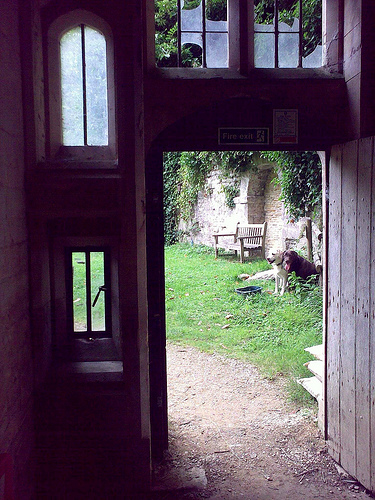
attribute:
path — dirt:
[74, 324, 372, 499]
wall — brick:
[165, 152, 321, 282]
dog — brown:
[279, 247, 319, 285]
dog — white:
[243, 247, 289, 298]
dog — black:
[269, 247, 286, 292]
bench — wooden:
[210, 217, 269, 264]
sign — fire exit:
[216, 127, 269, 144]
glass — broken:
[154, 0, 227, 68]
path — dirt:
[167, 339, 372, 486]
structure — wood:
[327, 137, 374, 494]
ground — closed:
[321, 112, 340, 137]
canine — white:
[265, 246, 290, 295]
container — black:
[230, 281, 273, 297]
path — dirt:
[174, 325, 311, 470]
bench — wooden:
[199, 211, 298, 286]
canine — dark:
[281, 248, 316, 282]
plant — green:
[161, 148, 328, 254]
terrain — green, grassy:
[166, 245, 324, 374]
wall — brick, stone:
[192, 170, 278, 198]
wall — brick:
[176, 161, 311, 266]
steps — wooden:
[295, 339, 328, 431]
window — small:
[58, 245, 113, 348]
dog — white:
[264, 249, 284, 297]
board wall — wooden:
[330, 147, 373, 474]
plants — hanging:
[167, 150, 328, 240]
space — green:
[171, 247, 315, 365]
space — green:
[167, 238, 323, 359]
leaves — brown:
[217, 309, 240, 330]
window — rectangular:
[66, 242, 110, 346]